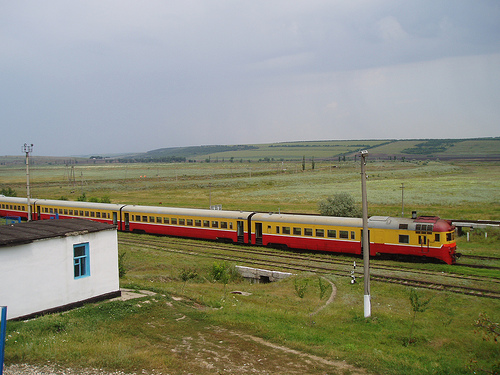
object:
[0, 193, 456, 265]
train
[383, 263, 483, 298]
tracks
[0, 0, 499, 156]
sky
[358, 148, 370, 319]
pole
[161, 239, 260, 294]
grass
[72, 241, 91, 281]
window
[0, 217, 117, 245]
roof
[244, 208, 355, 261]
car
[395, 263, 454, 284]
concrete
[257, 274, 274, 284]
entrance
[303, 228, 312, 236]
window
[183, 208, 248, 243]
side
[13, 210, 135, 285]
buliding